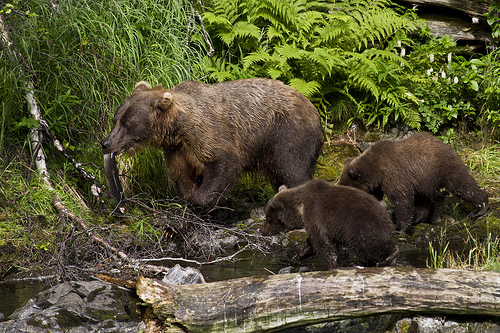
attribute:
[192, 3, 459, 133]
vegetation — green, leafy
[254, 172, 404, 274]
cubs — baby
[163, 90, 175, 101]
ear top — white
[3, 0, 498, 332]
scene — outdoors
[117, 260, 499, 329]
log — wood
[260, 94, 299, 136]
bear's fur — brown, black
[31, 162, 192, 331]
branch — broken